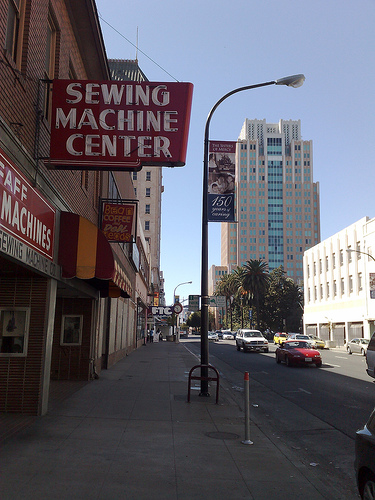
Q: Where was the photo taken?
A: Street.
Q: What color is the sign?
A: Red.